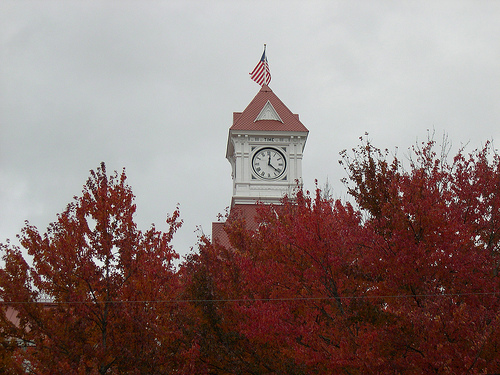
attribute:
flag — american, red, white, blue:
[250, 53, 280, 88]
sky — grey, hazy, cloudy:
[44, 23, 471, 97]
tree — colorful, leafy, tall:
[218, 249, 438, 358]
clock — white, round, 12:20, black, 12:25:
[250, 143, 286, 188]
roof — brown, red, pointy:
[238, 108, 300, 135]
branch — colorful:
[95, 268, 115, 334]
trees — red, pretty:
[56, 194, 494, 359]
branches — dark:
[89, 281, 117, 351]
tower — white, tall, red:
[224, 81, 315, 253]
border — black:
[248, 144, 256, 177]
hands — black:
[266, 154, 277, 171]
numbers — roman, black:
[257, 161, 265, 179]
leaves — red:
[139, 256, 174, 316]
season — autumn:
[122, 218, 348, 288]